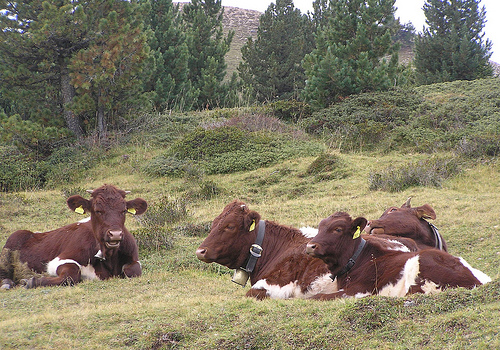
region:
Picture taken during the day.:
[26, 17, 498, 199]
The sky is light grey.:
[236, 8, 486, 65]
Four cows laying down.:
[52, 164, 488, 293]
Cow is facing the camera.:
[37, 199, 232, 321]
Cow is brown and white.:
[206, 226, 343, 348]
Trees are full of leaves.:
[39, 10, 280, 127]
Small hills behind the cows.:
[206, 83, 473, 196]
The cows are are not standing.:
[31, 157, 437, 337]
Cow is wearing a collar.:
[241, 188, 287, 327]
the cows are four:
[8, 178, 446, 308]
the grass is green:
[82, 281, 227, 341]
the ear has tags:
[335, 216, 382, 246]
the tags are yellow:
[337, 220, 377, 245]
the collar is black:
[226, 215, 276, 266]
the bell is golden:
[211, 235, 266, 291]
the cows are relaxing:
[65, 175, 492, 305]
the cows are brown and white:
[218, 181, 443, 283]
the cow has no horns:
[308, 208, 475, 295]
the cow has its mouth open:
[21, 191, 168, 306]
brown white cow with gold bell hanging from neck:
[192, 188, 305, 302]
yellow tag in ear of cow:
[65, 200, 93, 221]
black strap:
[240, 200, 278, 281]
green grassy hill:
[144, 110, 329, 190]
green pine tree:
[229, 3, 326, 108]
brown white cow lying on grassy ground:
[7, 190, 151, 297]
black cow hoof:
[25, 273, 49, 288]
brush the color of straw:
[370, 158, 456, 195]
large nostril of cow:
[296, 239, 326, 256]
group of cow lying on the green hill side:
[7, 163, 479, 321]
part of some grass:
[139, 301, 216, 337]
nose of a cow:
[302, 240, 324, 255]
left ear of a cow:
[228, 202, 263, 234]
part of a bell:
[232, 267, 249, 300]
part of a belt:
[251, 225, 272, 240]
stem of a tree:
[64, 91, 87, 119]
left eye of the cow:
[229, 225, 241, 239]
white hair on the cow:
[403, 262, 420, 282]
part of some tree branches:
[304, 25, 354, 72]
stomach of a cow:
[393, 250, 433, 285]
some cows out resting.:
[0, 95, 499, 321]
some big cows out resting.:
[0, 131, 494, 328]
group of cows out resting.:
[2, 129, 494, 324]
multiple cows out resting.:
[0, 128, 487, 327]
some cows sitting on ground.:
[1, 118, 488, 325]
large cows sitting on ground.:
[2, 145, 492, 320]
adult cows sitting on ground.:
[0, 137, 492, 339]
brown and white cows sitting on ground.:
[0, 144, 488, 321]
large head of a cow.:
[188, 198, 270, 274]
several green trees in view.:
[0, 0, 495, 100]